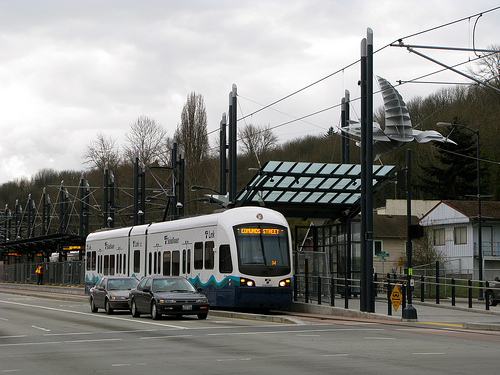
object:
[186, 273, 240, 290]
wave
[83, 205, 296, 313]
bus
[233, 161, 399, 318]
bus stop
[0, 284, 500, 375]
ground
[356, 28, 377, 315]
pole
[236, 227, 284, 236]
sign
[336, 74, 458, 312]
street lamp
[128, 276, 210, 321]
car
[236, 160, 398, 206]
roof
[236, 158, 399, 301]
shelter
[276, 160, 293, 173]
window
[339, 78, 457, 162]
sculpture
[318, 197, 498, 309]
houses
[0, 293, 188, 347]
line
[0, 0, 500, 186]
sky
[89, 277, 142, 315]
car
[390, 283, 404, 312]
sign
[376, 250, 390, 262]
sign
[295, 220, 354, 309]
fence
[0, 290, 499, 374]
street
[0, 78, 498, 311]
station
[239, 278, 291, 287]
lights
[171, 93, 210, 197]
tree top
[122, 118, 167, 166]
tree top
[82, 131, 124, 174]
tree top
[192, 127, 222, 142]
wire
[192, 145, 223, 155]
wire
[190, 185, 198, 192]
light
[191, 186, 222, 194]
pole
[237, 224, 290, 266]
windshield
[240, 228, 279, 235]
digital display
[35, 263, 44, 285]
person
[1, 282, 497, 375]
road